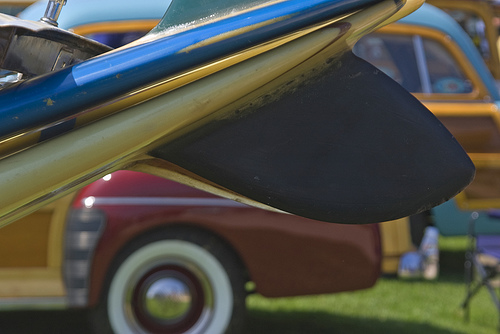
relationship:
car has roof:
[28, 4, 497, 287] [21, 3, 176, 20]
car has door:
[28, 4, 497, 287] [366, 29, 496, 204]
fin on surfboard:
[155, 56, 475, 219] [1, 0, 478, 210]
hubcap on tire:
[141, 278, 189, 324] [89, 225, 250, 334]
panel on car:
[442, 118, 500, 149] [28, 4, 497, 287]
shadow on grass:
[446, 248, 476, 282] [246, 279, 500, 334]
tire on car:
[89, 225, 250, 334] [28, 4, 497, 287]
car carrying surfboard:
[28, 4, 497, 287] [1, 0, 478, 210]